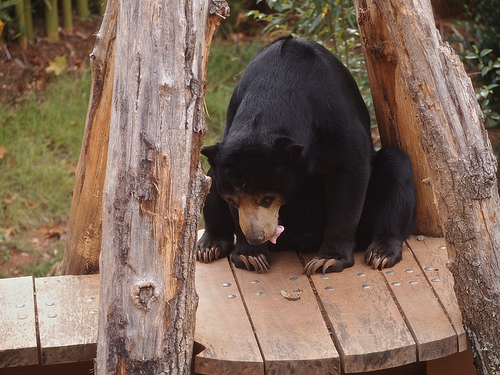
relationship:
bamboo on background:
[2, 2, 101, 38] [5, 4, 500, 40]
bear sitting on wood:
[187, 28, 425, 290] [198, 222, 470, 370]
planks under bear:
[198, 222, 470, 370] [187, 28, 425, 290]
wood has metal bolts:
[198, 222, 470, 370] [221, 263, 450, 304]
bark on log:
[119, 8, 187, 373] [95, 1, 212, 375]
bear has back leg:
[187, 28, 425, 290] [296, 163, 372, 276]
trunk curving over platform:
[379, 1, 500, 370] [198, 222, 470, 370]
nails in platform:
[193, 241, 400, 278] [198, 222, 470, 370]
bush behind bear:
[253, 4, 357, 34] [187, 28, 425, 290]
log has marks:
[95, 1, 212, 375] [132, 142, 191, 280]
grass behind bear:
[200, 33, 236, 107] [187, 28, 425, 290]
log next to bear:
[95, 1, 212, 375] [187, 28, 425, 290]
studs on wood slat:
[221, 263, 450, 304] [198, 222, 470, 370]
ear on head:
[197, 140, 225, 166] [189, 119, 314, 255]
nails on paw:
[301, 257, 336, 274] [301, 249, 354, 275]